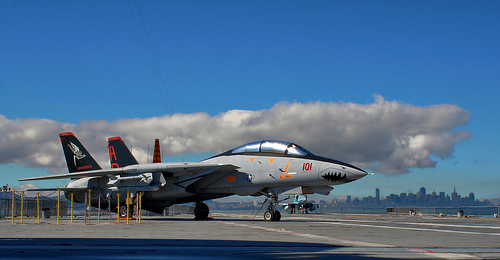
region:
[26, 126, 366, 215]
gray, red and black fighter jet on gray landing strip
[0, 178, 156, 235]
yellow marker poles on gray landing strip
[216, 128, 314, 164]
reflection on jet canopy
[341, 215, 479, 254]
gray landing strip with white stripes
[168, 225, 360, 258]
gray landing strip with white stripes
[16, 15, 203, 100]
clear blue sky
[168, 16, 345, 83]
clear blue sky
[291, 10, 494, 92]
clear blue sky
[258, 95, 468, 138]
gray and white clouds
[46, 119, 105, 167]
red, white and black tail of jet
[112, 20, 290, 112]
this is the sky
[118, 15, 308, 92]
the sky is blue in color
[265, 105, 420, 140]
this is a cloud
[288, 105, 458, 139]
the cloud is white in color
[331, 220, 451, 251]
this is a ground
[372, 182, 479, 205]
these are buildings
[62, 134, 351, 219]
this is a jet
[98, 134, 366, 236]
the jet is grey and blue in color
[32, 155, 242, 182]
these are wings of a jet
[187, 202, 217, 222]
this is the tyre's of a jet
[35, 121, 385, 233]
gray, red and black firther jet parked on gray landing strip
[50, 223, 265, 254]
gray landing strip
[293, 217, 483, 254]
gray landing strip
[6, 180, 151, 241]
yellow poles on gray landing strip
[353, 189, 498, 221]
brown buildings in distance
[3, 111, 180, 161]
white and gray clouds behind jet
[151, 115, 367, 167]
white and gray clouds behind jet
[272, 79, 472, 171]
white and gray clouds behind jet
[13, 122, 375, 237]
a plane in an airport.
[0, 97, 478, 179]
a huge grey cloud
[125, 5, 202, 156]
overhead electrical cables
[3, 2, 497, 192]
a blue sky with clouds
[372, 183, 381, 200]
a very tall building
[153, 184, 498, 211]
a lovely city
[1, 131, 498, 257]
a nice airport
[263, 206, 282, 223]
the wheel of an airplane.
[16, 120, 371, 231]
a plane about to fly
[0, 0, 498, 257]
a lovely daytime scene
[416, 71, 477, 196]
sky is cloudy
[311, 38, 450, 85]
most of the sky is blue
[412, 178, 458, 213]
city skyline in the background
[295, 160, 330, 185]
101 written on plane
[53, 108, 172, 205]
wings are red and black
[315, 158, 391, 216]
teeth drawn on front of plane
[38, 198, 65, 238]
a trashcan behind plane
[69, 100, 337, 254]
the plane is on the ground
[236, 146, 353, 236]
there are orange stickers on the plane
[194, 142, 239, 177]
the plane is grey and black